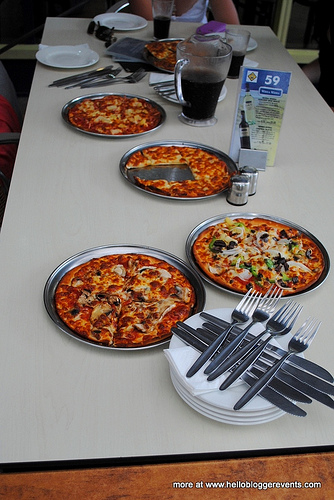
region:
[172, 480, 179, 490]
white print style letter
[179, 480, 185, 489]
white print style letter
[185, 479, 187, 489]
white print style letter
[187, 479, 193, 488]
white print style letter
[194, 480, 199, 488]
white print style letter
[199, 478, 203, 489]
white print style letter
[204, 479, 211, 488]
white print style letter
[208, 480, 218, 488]
white print style letter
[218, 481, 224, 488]
white print style letter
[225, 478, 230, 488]
white print style letter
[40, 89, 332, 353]
four pizzas on pans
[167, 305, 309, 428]
stack of white plates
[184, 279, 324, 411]
four silver forks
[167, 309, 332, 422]
five butter knifes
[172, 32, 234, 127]
glass pitcher of soda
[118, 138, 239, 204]
pizza with some missing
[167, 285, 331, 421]
forks stacked ontop knifes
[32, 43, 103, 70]
an empty white plate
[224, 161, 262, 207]
two short silver containers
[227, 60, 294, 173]
a drink menu on the table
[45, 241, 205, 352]
the pizza is on a plate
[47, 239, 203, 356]
the plate is made of metal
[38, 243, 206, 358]
the plate is grey in color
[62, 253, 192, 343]
the pizza has a crust on the border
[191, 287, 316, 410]
forks are on the plates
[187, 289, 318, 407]
the forks are made of metal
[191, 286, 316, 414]
the forks are shiny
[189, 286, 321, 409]
the forks are made of steel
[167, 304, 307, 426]
the plates are piled up on the table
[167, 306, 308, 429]
the plates are white in color